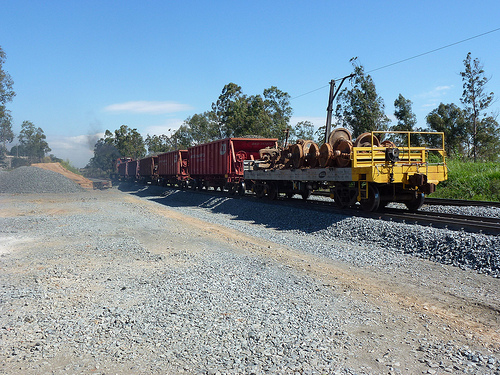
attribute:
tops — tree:
[217, 79, 299, 120]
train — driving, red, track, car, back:
[158, 90, 458, 205]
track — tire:
[240, 170, 362, 203]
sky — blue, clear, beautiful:
[194, 19, 266, 44]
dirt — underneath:
[236, 231, 308, 264]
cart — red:
[187, 133, 271, 193]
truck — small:
[284, 98, 401, 215]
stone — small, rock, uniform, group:
[423, 233, 445, 246]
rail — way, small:
[414, 206, 488, 242]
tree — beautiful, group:
[169, 69, 313, 137]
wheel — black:
[304, 181, 387, 214]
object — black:
[243, 147, 281, 187]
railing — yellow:
[341, 127, 440, 181]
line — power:
[392, 30, 446, 79]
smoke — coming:
[88, 110, 119, 168]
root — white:
[248, 130, 327, 172]